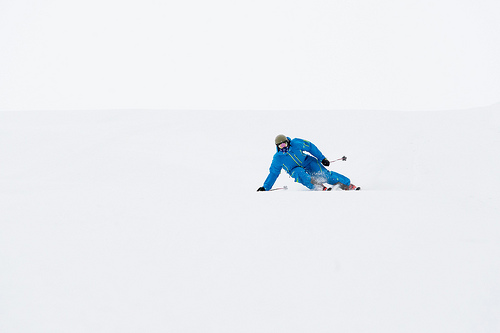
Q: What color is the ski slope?
A: White.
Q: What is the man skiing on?
A: Snow.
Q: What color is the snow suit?
A: Blue.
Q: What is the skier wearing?
A: A snowsuit.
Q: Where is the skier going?
A: Down the hill.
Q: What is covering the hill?
A: Snow.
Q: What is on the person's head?
A: A hat.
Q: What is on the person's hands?
A: Gloves.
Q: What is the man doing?
A: Skiing.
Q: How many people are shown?
A: One.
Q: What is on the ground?
A: Snow.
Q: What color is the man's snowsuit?
A: Blue.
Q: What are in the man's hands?
A: Poles.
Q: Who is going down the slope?
A: A man.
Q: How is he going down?
A: On ski;s.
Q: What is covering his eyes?
A: Goggles.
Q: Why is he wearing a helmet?
A: Head protection.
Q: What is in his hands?
A: Ski poles.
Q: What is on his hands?
A: Gloves.